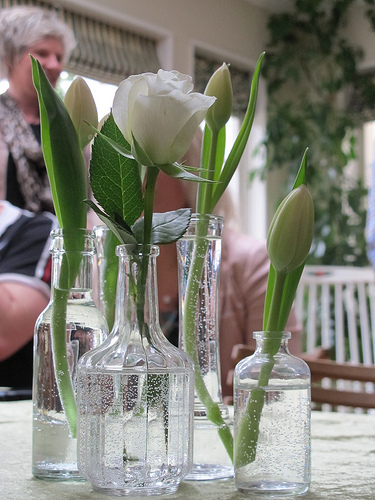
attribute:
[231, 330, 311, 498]
jar — glass, small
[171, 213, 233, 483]
jar — glass, small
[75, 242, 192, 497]
jar — glass, small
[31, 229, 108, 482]
jar — glass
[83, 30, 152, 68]
blinds — striped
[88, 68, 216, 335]
stem — green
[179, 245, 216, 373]
vases — clear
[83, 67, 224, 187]
rose — white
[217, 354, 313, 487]
clear jar — small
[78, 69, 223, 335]
rose — white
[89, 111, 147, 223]
leaf — green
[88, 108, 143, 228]
leaf — green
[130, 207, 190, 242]
leaf — green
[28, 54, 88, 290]
leaf — green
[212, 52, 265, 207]
leaf — green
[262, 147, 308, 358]
leaf — green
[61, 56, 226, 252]
green leaf — long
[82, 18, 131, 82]
curtain — striped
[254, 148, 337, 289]
plant — small, green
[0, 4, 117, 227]
woman — gray-haired